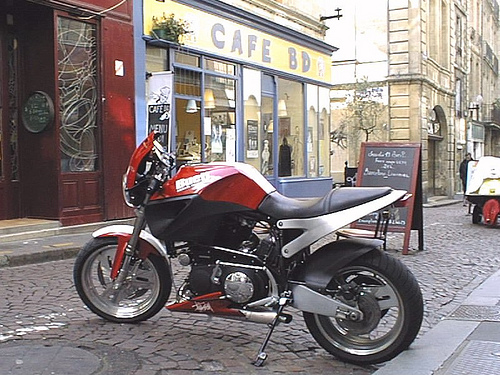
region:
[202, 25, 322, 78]
the sign says cafe bd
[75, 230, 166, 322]
front wheel of motorcycle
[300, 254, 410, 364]
back wheel of motorcycle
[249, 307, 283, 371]
kickstand of the motorcycle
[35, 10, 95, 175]
glass in the door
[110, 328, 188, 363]
bricks on the ground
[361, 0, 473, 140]
ladder on the building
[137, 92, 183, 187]
handlebars of the motorcycle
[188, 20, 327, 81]
sign for the cafe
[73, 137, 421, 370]
a motorcycle in the foreground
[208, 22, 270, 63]
the word CAFE in capital letter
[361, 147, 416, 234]
the menu of the Cafe BD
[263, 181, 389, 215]
the seat of the motorcycle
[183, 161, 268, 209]
the gas tank of the motorcycle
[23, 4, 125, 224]
this house is brown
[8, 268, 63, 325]
a cobblestone street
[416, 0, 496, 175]
the facade of an old building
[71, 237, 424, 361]
the tires of the motorcycle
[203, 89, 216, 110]
looks like a yellow lamp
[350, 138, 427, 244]
chalkboard easel sign outside restaurant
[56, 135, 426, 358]
motorcycle is parked in the street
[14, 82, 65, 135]
sign hung on a wall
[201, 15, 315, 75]
restaurant name above the glass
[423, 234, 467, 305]
cobblestone street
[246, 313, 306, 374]
motorcycle is leaning on the kick stand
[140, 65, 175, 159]
banner hanging on the wall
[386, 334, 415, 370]
tire is leaning against the curb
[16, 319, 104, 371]
manhole in the street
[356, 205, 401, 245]
chair by the sign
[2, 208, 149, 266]
gray colored concrete sidewalk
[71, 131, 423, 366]
a red and black sidewalk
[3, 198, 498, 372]
a cobblestone roadway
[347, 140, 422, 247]
a red and black sandwich sign with white writing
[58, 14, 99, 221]
a door with decorative glass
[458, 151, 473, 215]
a person wearing a black shirt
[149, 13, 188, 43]
a flower in a planter box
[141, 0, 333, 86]
a yellow sign that says "Cafe Bd"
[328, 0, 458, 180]
a yellow colored rock building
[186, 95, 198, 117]
a white colored lamp shade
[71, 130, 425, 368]
Red, black and silver motorcyle parked in middle of the road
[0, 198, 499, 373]
Cobble stone road in the middle of a city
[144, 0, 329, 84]
Yellow and blue sign on top of corner cafe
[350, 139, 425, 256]
Sign in front of cafe in middle of the road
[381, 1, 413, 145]
Ladder on old building in background of the picture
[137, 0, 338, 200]
Corner cafe on the side of the road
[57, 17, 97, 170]
Window with carved glass in store on side of the road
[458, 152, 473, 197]
Person walking down the cobblestone road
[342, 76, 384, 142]
Tree growing in front of old building in the background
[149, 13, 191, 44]
Flower pot next to sign of corner cafe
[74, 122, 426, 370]
A red, black, and silver motorcycle.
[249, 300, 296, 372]
A black kickstand on a motorcycle.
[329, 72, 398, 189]
A tree without leaves.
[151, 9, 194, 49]
A plant hanging up on the side of a building.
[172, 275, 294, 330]
A silver exhaust on a motorcycle.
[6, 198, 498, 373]
A grey bricked road.